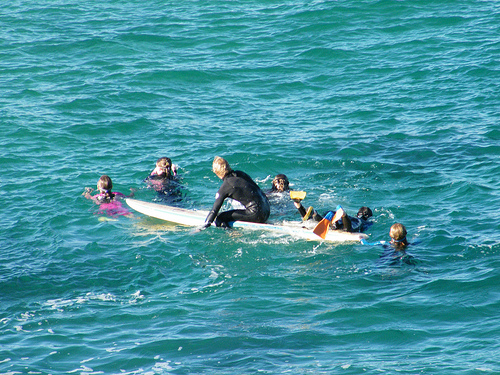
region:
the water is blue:
[24, 17, 478, 374]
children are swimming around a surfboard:
[55, 140, 416, 284]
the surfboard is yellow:
[126, 182, 371, 265]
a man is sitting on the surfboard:
[116, 150, 377, 267]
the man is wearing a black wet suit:
[194, 150, 271, 234]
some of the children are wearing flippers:
[280, 173, 383, 265]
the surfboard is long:
[84, 175, 402, 276]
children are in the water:
[58, 137, 452, 288]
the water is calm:
[12, 8, 444, 343]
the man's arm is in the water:
[176, 152, 284, 262]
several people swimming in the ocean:
[51, 126, 444, 307]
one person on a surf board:
[75, 142, 427, 281]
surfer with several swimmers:
[66, 138, 442, 280]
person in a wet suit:
[193, 150, 283, 257]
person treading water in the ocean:
[63, 147, 130, 237]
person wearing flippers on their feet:
[283, 187, 339, 251]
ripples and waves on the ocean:
[108, 78, 313, 116]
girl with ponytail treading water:
[379, 218, 441, 282]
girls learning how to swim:
[65, 134, 456, 309]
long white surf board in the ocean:
[120, 195, 375, 246]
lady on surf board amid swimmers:
[62, 120, 429, 288]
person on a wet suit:
[194, 145, 281, 245]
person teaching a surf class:
[194, 137, 306, 269]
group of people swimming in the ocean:
[69, 113, 427, 301]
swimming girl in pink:
[67, 171, 145, 236]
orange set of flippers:
[288, 188, 348, 256]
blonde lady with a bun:
[196, 146, 293, 253]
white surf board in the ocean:
[119, 191, 375, 256]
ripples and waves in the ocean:
[145, 46, 385, 101]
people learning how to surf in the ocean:
[60, 124, 472, 293]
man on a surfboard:
[125, 146, 375, 256]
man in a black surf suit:
[190, 140, 265, 245]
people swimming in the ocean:
[80, 140, 425, 265]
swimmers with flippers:
[280, 180, 375, 235]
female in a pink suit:
[70, 160, 130, 230]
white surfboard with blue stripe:
[127, 191, 367, 256]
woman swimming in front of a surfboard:
[57, 155, 147, 241]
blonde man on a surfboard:
[196, 136, 285, 267]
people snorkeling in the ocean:
[288, 181, 375, 252]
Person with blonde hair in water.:
[383, 217, 415, 264]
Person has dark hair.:
[353, 200, 383, 220]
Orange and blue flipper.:
[311, 210, 359, 249]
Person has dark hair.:
[273, 168, 295, 205]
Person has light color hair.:
[207, 141, 234, 186]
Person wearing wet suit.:
[213, 165, 263, 240]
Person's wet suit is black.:
[211, 185, 269, 226]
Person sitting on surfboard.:
[207, 208, 296, 255]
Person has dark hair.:
[156, 148, 200, 213]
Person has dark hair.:
[88, 170, 138, 224]